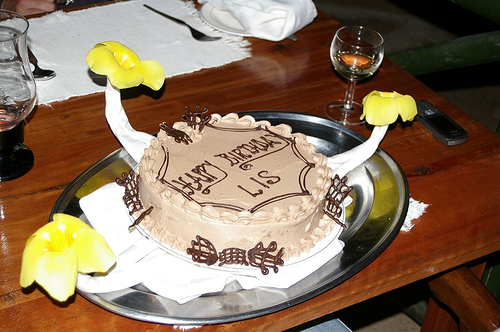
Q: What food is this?
A: Cake.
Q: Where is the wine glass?
A: Right of cake.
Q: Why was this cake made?
A: For a birthday.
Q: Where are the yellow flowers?
A: On the cake.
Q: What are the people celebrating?
A: Birthday.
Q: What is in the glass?
A: Wine.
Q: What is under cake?
A: Metal plate.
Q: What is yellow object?
A: Flower.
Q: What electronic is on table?
A: Cellphone.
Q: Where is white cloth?
A: On table.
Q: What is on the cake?
A: Frosting.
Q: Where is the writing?
A: On cake top.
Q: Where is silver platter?
A: Under cake.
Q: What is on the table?
A: Placemat.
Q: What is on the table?
A: A cake.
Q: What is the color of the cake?
A: Brown.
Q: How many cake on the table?
A: One.